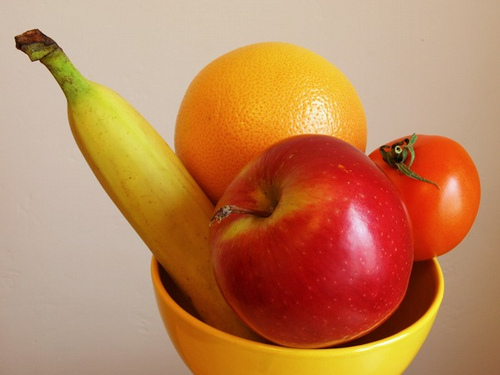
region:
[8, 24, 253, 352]
The banana is yellow.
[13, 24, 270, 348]
The banana is ripe.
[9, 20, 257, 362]
The banana is unpeeled.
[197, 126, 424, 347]
The apple is red.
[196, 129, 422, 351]
The apple is round.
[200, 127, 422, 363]
The apple is ripe.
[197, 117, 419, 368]
The apple is unpeeled.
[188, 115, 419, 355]
The apple has the stem on it.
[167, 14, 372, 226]
The orange is round.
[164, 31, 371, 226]
The orange is unpeeled.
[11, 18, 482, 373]
The fruit is in a bowl.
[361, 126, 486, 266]
The tomato is red.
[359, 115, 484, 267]
The tomato has a stem.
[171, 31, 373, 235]
The orange is unpeeled.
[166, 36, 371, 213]
The orange is round.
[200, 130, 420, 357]
The apple is round.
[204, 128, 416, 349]
The apple is unpeeled.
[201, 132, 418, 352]
The apple is red.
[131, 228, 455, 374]
The bowl is yellow.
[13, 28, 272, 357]
The banana is yellow.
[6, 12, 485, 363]
A group of fruit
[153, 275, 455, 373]
A yellow bowl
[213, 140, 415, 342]
A red and green apple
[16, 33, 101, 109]
A green banana stem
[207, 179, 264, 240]
A brown apple stem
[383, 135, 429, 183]
A green tomato stem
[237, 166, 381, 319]
A red apple in the yellow cup.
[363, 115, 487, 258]
Tomatoe in the bowl.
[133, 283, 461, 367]
The cup is yellow.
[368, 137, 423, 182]
Green stem on the tomatoe.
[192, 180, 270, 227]
The stem on the apple.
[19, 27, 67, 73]
Green stem on the banana.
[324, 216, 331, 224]
white spot on apple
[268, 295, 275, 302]
white spot on apple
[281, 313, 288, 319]
white spot on apple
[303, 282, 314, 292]
white spot on apple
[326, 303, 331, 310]
white spot on apple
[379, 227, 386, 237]
white spot on apple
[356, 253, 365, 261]
white spot on apple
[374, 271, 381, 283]
white spot on apple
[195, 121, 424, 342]
a ripe red apple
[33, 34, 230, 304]
a long straight banana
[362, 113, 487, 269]
a ripe plump tomato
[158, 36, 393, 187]
a smooth ripe orange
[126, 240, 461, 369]
a yellow ceramic bowl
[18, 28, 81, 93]
Green and black stem of fruit.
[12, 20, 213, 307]
Long, yellow, unblemished banana.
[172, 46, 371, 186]
Large, round orange.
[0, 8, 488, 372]
Close-up of fruit, against neutral backdrop.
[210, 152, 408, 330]
Large, red and green apple.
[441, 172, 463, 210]
Shine on tomato, indicating daylight.